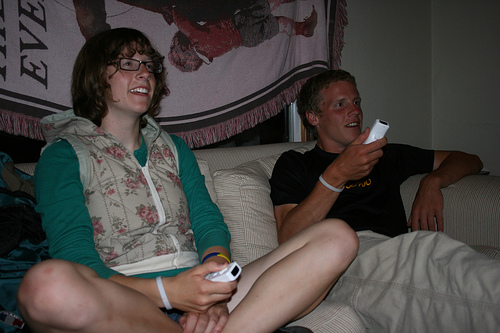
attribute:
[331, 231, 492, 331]
sheet — covering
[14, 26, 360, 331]
girl — wearing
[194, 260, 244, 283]
controller — white,  black 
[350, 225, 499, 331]
blanket — beige , part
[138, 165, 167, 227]
zipper — White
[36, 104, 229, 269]
jacket — woman's, Green, printed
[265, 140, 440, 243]
t shirt — black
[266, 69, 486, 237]
young man — playing 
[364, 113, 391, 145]
wii — video,  game , controller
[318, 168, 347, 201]
whiteband — wearing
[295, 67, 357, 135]
hair — brown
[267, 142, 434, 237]
shirt —  black 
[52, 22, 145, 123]
hair — brown 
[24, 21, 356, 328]
woman — holding, wearing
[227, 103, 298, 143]
window — part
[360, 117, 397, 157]
controller — black , White 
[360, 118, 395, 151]
controller — wii, white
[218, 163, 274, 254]
pillow — White 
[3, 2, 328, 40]
blanket — large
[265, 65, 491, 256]
man — wearing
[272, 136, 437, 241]
t-shirt — black 